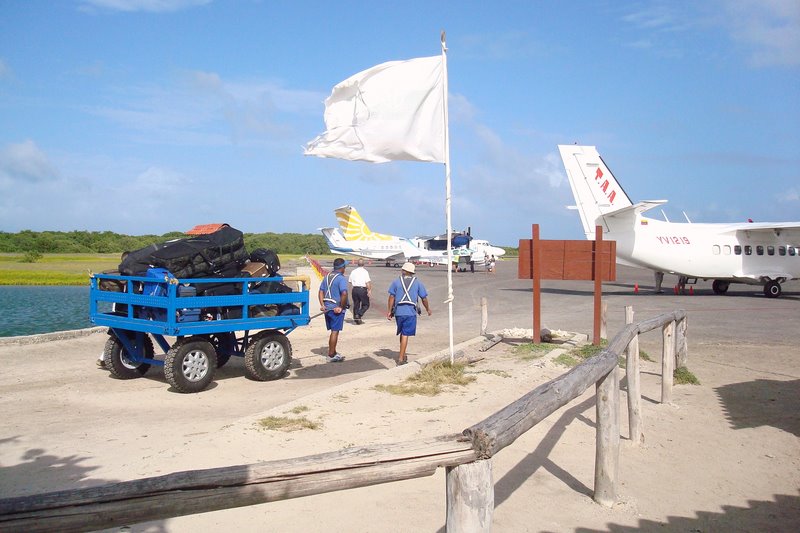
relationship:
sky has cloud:
[2, 0, 798, 244] [82, 0, 208, 12]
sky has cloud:
[2, 0, 798, 244] [5, 137, 61, 182]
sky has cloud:
[2, 0, 798, 244] [104, 72, 325, 150]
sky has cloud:
[2, 0, 798, 244] [621, 3, 797, 70]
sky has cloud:
[2, 0, 798, 244] [454, 93, 575, 225]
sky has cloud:
[2, 0, 798, 244] [684, 149, 798, 167]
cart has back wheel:
[90, 269, 309, 393] [166, 338, 217, 393]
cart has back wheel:
[90, 269, 309, 393] [105, 333, 151, 377]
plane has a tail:
[559, 144, 797, 296] [563, 145, 637, 248]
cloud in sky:
[454, 93, 575, 225] [2, 0, 798, 244]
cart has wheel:
[90, 269, 309, 393] [243, 331, 292, 381]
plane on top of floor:
[559, 144, 797, 296] [0, 262, 796, 533]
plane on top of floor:
[328, 208, 505, 272] [0, 262, 796, 533]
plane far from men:
[328, 208, 505, 272] [321, 256, 433, 365]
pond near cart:
[0, 285, 104, 336] [90, 269, 309, 393]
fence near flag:
[2, 315, 692, 532] [304, 36, 456, 363]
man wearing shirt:
[384, 262, 433, 366] [391, 281, 425, 314]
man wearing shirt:
[321, 257, 350, 361] [322, 275, 351, 314]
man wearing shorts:
[384, 262, 433, 366] [396, 315, 419, 337]